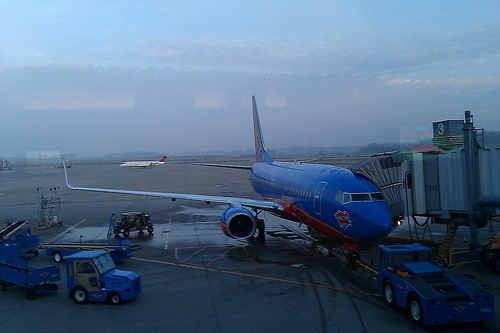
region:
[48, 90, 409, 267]
large blue jet plane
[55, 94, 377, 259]
large plane on tarmac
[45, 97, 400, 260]
large plane parked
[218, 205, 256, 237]
blue jet engine of plane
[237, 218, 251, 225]
black turbines inside engine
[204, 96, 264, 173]
blue and red tail fin of plane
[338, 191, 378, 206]
window on top of plane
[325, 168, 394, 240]
cockpit of large plane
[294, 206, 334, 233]
red stripe on bottom of plane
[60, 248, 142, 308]
vehicle driving on tarmac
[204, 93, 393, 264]
A blue plane at the terminal.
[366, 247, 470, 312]
Blue cart to pull the plane.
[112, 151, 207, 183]
White plane on the runway.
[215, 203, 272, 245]
The engine of the plane.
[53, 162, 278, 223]
The wing of the plane.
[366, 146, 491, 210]
The terminal walkway of the airport.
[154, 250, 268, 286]
Yellow line on the pavement.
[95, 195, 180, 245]
A luggage cart on the terminal.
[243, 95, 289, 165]
The tail of the plane.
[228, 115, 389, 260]
The plane is red and blue.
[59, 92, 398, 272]
A blue and red airplane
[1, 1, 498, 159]
The sky is overcast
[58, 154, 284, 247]
Wing of an airplane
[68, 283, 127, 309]
Two round black tires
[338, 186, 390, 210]
Front windows of a plane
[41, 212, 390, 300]
Yellow lines on the tarmac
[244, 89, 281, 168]
Tail of a plane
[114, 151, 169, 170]
White airplane in the background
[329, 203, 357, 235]
Red symbol on the plane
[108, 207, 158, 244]
A vehicle on the tarmac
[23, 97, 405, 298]
a blue and red plane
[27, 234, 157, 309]
a little blue vehicle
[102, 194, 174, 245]
a little black vehicle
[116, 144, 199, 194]
a white and red plane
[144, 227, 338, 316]
yellow lines on the pavement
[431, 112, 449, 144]
a white number 3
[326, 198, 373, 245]
red design on blue plane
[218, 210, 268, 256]
a blue and red jet engine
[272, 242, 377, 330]
black lines on the pavement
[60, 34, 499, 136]
white clouds in the sky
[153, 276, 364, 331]
The ground is made of concrete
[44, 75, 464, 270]
The plane is on the ground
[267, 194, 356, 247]
The plane is red on the bottom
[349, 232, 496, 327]
The car on the ground is blue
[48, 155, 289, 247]
The wing of the airplane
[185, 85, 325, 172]
The tail of the airplane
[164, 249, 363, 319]
The line on the ground is yellow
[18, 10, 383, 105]
The sky is blue and grey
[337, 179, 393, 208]
The window to the cockpit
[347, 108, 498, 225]
The entrance to the plane